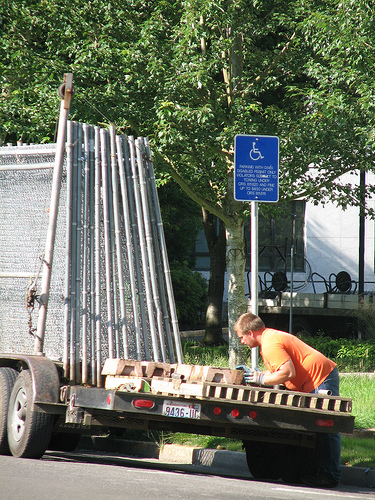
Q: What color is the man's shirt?
A: Orange.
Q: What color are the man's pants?
A: Blue.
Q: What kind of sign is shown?
A: Handicapped.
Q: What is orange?
A: Man's shirt.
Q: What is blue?
A: A sign.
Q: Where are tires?
A: On a truck.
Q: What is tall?
A: Trees.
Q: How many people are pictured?
A: One.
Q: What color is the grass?
A: Green.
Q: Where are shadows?
A: On the ground.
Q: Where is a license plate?
A: On back of truck.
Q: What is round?
A: Tires.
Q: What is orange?
A: Man's shirt.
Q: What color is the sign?
A: Blue.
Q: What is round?
A: Tires.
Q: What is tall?
A: Trees.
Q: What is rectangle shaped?
A: License plate.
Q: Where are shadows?
A: On the ground.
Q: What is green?
A: Grass.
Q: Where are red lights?
A: On back of the truck.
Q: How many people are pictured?
A: One.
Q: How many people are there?
A: 1.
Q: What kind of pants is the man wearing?
A: Jeans.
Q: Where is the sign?
A: Behind the man.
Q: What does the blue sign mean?
A: Handicap parking.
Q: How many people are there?
A: One.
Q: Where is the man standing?
A: Next to the truck bed.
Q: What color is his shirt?
A: Orange.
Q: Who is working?
A: The man in orange.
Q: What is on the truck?
A: Fences.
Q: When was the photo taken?
A: During the day.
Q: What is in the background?
A: Trees and a building.